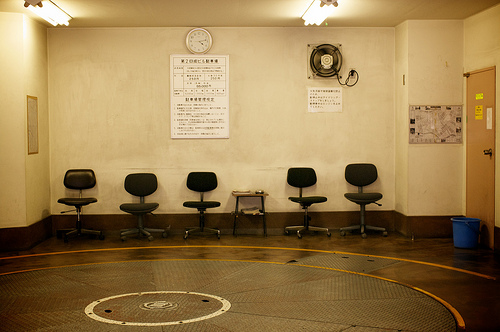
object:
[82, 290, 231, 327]
circle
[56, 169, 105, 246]
chair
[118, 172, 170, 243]
chair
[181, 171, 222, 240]
chair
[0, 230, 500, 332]
floor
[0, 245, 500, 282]
lines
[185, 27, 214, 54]
clock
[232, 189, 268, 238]
table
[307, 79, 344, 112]
sign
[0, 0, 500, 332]
warehouse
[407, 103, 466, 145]
safety poster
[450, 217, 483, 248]
basket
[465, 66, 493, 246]
door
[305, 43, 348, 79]
fan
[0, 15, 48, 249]
wall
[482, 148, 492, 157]
door handle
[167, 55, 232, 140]
sign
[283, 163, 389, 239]
two chairs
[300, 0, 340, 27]
fixture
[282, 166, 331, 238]
chair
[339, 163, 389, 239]
chair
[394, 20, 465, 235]
wall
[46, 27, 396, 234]
wall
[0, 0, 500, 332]
office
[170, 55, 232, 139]
directory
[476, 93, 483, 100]
sign